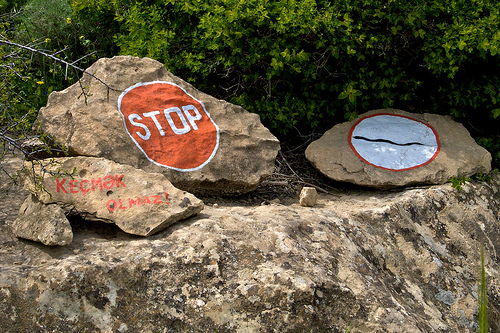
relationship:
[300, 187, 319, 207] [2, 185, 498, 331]
rock sitting on rock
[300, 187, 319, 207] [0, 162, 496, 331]
rock on a rock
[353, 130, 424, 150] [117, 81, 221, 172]
image of a stop sign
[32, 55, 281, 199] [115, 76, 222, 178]
rock with a stop sign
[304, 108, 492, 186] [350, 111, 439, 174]
rock with a sign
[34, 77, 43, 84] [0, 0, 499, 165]
flower in woods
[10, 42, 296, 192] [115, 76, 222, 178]
rock has stop sign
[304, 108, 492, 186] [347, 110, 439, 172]
rock has circle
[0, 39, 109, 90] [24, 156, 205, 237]
tree branch hangs over rock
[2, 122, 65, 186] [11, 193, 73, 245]
branch hangs over rock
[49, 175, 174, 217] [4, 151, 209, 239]
writing on rock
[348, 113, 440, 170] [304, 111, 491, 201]
art on rock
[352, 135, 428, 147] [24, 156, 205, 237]
snake on rock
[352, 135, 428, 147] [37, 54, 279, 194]
snake on rock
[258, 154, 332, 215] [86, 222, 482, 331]
sticks on rock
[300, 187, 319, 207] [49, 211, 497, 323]
rock on rock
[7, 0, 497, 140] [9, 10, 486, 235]
trees in background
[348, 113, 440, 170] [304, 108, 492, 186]
art on rock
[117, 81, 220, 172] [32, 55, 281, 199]
art on rock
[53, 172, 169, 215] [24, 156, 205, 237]
graffiti on rock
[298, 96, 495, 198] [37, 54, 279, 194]
rock on rock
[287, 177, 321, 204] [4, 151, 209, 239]
rock on rock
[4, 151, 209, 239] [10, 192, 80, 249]
rock on rock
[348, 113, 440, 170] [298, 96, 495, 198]
art on rock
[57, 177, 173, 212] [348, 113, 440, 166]
artist name on art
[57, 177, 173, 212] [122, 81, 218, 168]
artist name on art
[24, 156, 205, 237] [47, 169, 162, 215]
rock has foreign words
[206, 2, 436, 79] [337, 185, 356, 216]
foliage in ground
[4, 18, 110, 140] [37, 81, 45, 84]
plant has flower